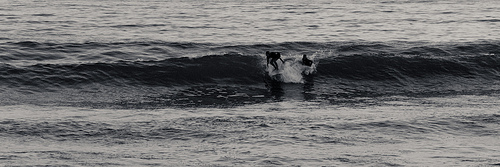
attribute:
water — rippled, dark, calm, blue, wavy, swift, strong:
[1, 1, 500, 165]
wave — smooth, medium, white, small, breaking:
[63, 55, 500, 86]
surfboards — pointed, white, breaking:
[269, 68, 317, 79]